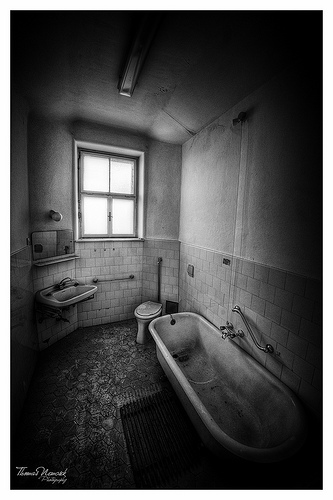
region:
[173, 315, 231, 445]
a bathtub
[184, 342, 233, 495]
a bathtub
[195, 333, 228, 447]
a bathtub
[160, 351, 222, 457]
a bathtub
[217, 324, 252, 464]
a bathtub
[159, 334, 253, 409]
A dirty bathtube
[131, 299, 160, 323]
A toilet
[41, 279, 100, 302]
A bathroom sink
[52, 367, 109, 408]
The tile on the floor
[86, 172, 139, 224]
A window in the bathroom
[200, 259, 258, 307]
the tile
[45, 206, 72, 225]
A light on the wall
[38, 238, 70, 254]
the small mirror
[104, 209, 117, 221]
A cross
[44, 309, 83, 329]
pipes under the sink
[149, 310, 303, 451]
the long bath tub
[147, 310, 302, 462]
the long and dirty bath tub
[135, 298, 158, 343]
the dirty toilet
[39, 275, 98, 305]
the dirty sink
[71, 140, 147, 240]
the bathroom window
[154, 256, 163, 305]
the pipe behind the toilet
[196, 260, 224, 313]
the tiles on the wall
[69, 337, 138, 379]
the tiles on the ground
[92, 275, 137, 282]
the metal rod on the wall near the toilet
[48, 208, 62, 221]
the light above the sink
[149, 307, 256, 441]
The bathtub is dirty.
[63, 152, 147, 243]
The window is in the bathroom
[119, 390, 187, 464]
A rug is in front of the tub.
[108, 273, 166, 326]
The dirty toilet lid is closed.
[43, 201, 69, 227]
A light above the sink.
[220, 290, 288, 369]
Railing on the side of the tub.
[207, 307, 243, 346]
Faucets on the wall.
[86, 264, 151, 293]
The railing on the wall.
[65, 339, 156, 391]
The tile floor is dirty.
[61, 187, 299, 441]
The picture is black and white.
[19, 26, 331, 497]
a scene inside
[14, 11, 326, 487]
a scene happening during the day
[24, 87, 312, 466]
a scene of a bathroom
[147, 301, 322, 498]
a long bathtub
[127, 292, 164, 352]
a white toilet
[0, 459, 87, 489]
a watermark of the artist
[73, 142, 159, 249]
a window on the back wall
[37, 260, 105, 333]
a white sink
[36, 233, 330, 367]
some tiles on the walls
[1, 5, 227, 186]
an arch roof